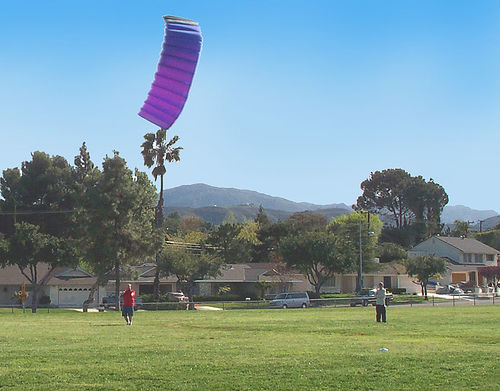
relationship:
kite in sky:
[139, 14, 201, 128] [208, 9, 489, 161]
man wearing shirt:
[113, 281, 138, 325] [119, 288, 137, 306]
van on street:
[267, 290, 311, 311] [234, 298, 494, 310]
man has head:
[113, 281, 138, 325] [126, 281, 133, 292]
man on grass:
[113, 281, 138, 325] [3, 306, 498, 391]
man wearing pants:
[369, 279, 393, 325] [373, 304, 389, 323]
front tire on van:
[279, 303, 289, 310] [267, 290, 311, 311]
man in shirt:
[113, 281, 138, 325] [119, 288, 137, 306]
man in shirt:
[369, 279, 393, 325] [373, 288, 388, 307]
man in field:
[113, 281, 138, 325] [1, 300, 500, 391]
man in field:
[369, 279, 393, 325] [1, 300, 500, 391]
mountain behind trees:
[150, 178, 499, 230] [145, 207, 496, 266]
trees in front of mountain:
[145, 207, 496, 266] [150, 178, 499, 230]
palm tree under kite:
[139, 126, 186, 225] [139, 14, 201, 128]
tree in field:
[2, 149, 89, 314] [1, 300, 500, 391]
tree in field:
[70, 151, 166, 311] [1, 300, 500, 391]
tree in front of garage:
[70, 151, 166, 311] [52, 285, 101, 308]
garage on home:
[52, 285, 101, 308] [1, 257, 100, 311]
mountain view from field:
[150, 178, 499, 230] [1, 300, 500, 391]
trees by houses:
[145, 207, 496, 266] [1, 224, 498, 308]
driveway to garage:
[61, 303, 107, 316] [52, 285, 101, 308]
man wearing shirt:
[369, 279, 393, 325] [373, 288, 388, 307]